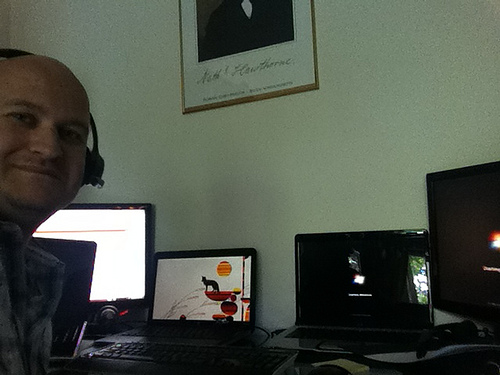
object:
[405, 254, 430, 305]
reflection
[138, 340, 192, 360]
keys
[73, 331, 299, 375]
keyboard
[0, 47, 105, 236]
head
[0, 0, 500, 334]
wall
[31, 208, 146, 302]
computer screen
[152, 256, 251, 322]
computer screen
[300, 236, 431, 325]
computer screen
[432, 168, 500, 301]
computer screen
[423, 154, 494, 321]
white bowl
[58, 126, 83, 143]
eyes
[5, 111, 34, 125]
eye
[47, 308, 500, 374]
desk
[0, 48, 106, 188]
headphones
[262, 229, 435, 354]
computer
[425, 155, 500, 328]
computer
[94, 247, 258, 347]
computer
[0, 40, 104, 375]
man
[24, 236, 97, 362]
computer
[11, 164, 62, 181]
mouth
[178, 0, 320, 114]
photo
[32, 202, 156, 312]
computer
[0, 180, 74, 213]
chin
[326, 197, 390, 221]
part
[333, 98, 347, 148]
part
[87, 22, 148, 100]
part